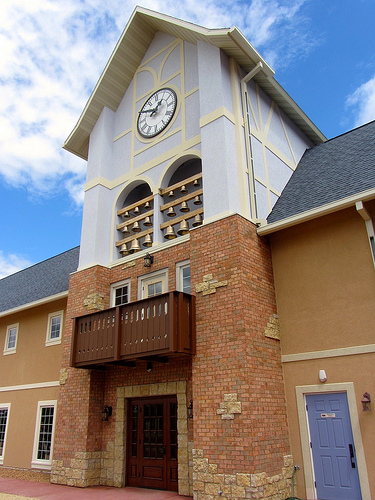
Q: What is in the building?
A: Balcony.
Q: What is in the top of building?
A: Clock.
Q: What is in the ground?
A: Windows.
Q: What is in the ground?
A: Bricsk.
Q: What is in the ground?
A: Wall.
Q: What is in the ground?
A: Wood.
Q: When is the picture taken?
A: 1:50.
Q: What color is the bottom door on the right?
A: Blue.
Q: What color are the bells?
A: Gold.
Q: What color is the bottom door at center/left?
A: Brown.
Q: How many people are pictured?
A: None.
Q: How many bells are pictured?
A: Eighteen.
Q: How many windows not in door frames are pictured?
A: Six.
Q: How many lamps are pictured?
A: Four.